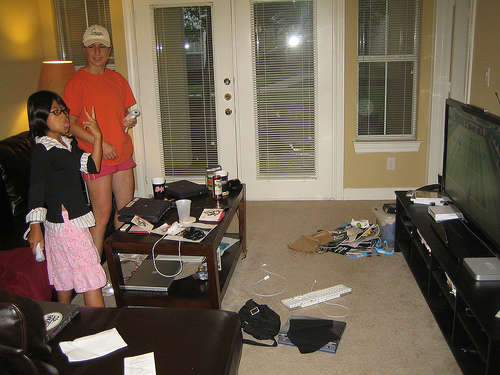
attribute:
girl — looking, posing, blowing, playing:
[23, 94, 120, 307]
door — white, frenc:
[253, 4, 315, 178]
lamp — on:
[33, 59, 81, 96]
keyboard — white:
[283, 276, 351, 300]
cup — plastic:
[175, 196, 191, 227]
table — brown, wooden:
[140, 178, 244, 305]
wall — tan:
[3, 4, 59, 140]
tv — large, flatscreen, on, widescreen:
[443, 97, 499, 250]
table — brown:
[396, 192, 499, 344]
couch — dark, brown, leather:
[2, 129, 70, 261]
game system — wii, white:
[428, 203, 454, 222]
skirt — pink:
[38, 219, 111, 293]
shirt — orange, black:
[66, 74, 138, 164]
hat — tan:
[81, 28, 112, 43]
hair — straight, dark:
[23, 92, 67, 131]